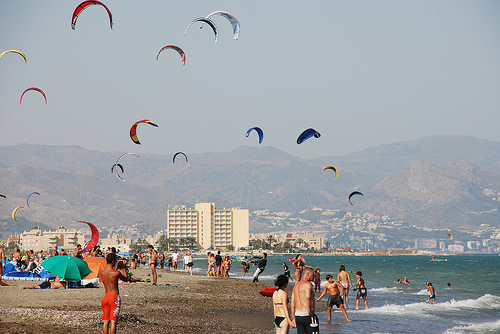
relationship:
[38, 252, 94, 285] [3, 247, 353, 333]
umbrella on beach